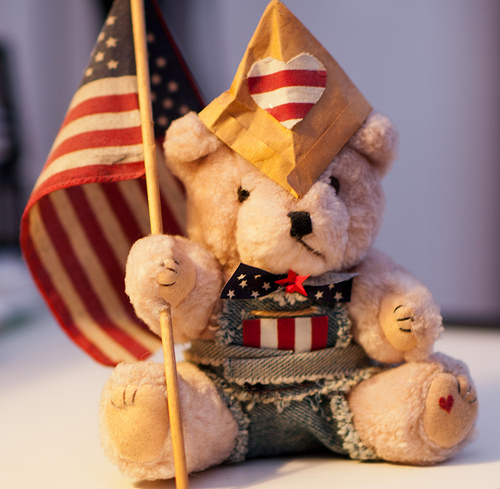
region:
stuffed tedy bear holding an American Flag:
[15, 4, 482, 481]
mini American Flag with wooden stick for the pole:
[12, 0, 194, 487]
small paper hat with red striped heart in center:
[193, 3, 374, 200]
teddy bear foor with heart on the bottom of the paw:
[406, 360, 488, 477]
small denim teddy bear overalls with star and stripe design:
[187, 264, 372, 474]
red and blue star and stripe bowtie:
[216, 254, 359, 307]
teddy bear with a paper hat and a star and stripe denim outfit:
[120, 22, 478, 482]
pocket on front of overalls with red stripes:
[236, 312, 336, 368]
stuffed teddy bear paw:
[358, 286, 440, 359]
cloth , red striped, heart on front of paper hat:
[243, 49, 331, 134]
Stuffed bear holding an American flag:
[4, 5, 484, 468]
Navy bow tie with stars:
[217, 257, 358, 308]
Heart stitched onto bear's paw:
[433, 390, 459, 416]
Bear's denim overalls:
[184, 267, 382, 459]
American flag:
[8, 7, 213, 479]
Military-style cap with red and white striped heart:
[183, 1, 400, 203]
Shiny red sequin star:
[274, 267, 314, 303]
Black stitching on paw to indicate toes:
[387, 298, 420, 340]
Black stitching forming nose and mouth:
[266, 204, 346, 272]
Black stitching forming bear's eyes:
[221, 171, 347, 202]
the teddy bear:
[90, 22, 419, 482]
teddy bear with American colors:
[21, 5, 475, 487]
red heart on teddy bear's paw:
[432, 391, 461, 419]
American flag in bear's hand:
[17, 3, 198, 382]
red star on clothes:
[276, 266, 311, 300]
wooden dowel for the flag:
[129, 70, 184, 486]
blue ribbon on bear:
[219, 259, 365, 318]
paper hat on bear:
[197, 0, 386, 201]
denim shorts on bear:
[208, 383, 366, 466]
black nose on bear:
[274, 208, 325, 239]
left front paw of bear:
[364, 286, 449, 363]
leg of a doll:
[394, 445, 404, 465]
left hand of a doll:
[385, 296, 395, 332]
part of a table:
[19, 376, 46, 429]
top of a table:
[475, 449, 476, 461]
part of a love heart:
[447, 402, 453, 409]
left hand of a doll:
[181, 284, 186, 290]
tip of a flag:
[103, 340, 116, 374]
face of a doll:
[264, 177, 326, 263]